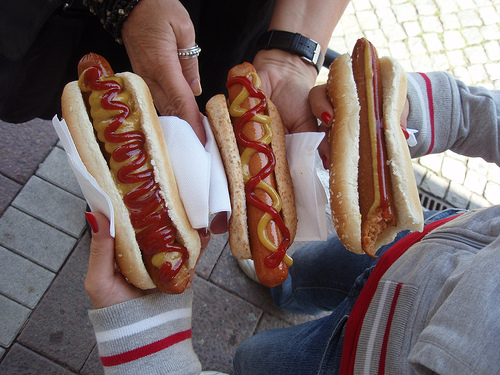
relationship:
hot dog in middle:
[204, 56, 300, 286] [197, 1, 312, 373]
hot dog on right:
[328, 35, 426, 259] [313, 0, 500, 374]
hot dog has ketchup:
[63, 51, 203, 292] [84, 66, 189, 280]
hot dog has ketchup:
[204, 56, 300, 286] [225, 78, 292, 268]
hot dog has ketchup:
[328, 35, 426, 259] [368, 40, 390, 219]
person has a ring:
[0, 0, 355, 194] [177, 44, 203, 61]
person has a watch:
[0, 0, 355, 194] [253, 27, 326, 77]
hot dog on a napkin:
[204, 56, 300, 286] [200, 116, 329, 240]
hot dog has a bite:
[328, 35, 426, 259] [362, 207, 400, 258]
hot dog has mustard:
[204, 56, 300, 286] [230, 71, 293, 266]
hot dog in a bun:
[204, 56, 300, 286] [202, 91, 299, 260]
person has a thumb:
[0, 0, 355, 194] [172, 22, 202, 97]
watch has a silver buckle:
[253, 27, 326, 77] [299, 35, 321, 64]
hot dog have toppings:
[225, 61, 289, 288] [79, 40, 390, 278]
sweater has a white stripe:
[87, 71, 500, 374] [86, 304, 193, 343]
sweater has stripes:
[87, 71, 500, 374] [401, 69, 437, 160]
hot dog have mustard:
[225, 61, 289, 288] [230, 71, 293, 266]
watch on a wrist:
[253, 27, 326, 77] [253, 13, 341, 80]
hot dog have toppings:
[204, 56, 300, 286] [79, 40, 390, 278]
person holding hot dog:
[0, 0, 355, 194] [204, 56, 300, 286]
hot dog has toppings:
[204, 56, 300, 286] [79, 40, 390, 278]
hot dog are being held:
[225, 61, 289, 288] [55, 0, 412, 304]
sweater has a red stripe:
[87, 71, 500, 374] [99, 327, 196, 368]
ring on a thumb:
[177, 44, 203, 61] [172, 22, 202, 97]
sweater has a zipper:
[87, 71, 500, 374] [418, 230, 491, 252]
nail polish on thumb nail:
[81, 210, 100, 238] [83, 211, 98, 233]